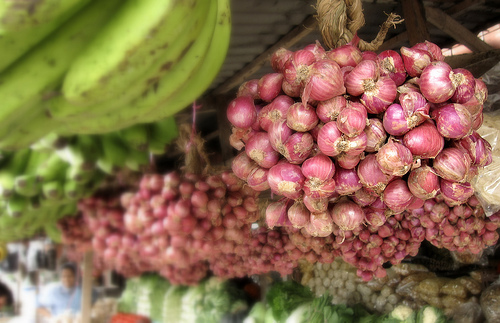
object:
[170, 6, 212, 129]
bananas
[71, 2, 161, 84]
bananas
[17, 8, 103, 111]
bananas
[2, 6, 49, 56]
bananas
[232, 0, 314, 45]
ceiling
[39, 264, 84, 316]
man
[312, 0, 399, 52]
rope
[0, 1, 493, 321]
market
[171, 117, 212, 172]
rope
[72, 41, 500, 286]
onions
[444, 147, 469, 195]
ground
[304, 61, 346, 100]
pink onion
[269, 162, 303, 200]
pink onion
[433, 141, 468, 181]
pink onion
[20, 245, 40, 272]
group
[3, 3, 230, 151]
plantains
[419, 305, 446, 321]
green vegetable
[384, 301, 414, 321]
green vegetable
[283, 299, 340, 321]
green vegetable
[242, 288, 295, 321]
green vegetable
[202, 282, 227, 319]
green vegetable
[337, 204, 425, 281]
bushel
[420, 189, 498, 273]
bushel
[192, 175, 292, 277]
bushel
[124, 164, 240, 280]
bushel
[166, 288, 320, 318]
bags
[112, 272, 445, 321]
celery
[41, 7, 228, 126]
banana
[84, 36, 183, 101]
spots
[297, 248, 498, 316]
wood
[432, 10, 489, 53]
support beam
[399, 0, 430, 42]
support beam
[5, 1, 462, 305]
stand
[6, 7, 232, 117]
collection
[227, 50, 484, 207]
ball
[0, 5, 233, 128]
bananas